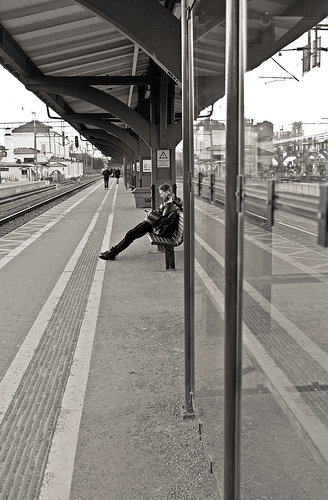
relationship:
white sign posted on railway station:
[142, 158, 151, 173] [0, 0, 326, 500]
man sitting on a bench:
[99, 183, 175, 260] [152, 220, 182, 269]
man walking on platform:
[102, 166, 111, 187] [70, 184, 129, 217]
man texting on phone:
[99, 183, 178, 260] [145, 209, 150, 215]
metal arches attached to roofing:
[27, 77, 157, 159] [1, 0, 171, 112]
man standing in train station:
[99, 166, 108, 186] [2, 0, 326, 281]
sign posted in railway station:
[151, 143, 201, 172] [0, 0, 326, 500]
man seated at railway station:
[99, 183, 175, 260] [0, 0, 327, 498]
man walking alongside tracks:
[102, 166, 111, 187] [0, 169, 104, 243]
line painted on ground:
[39, 179, 120, 497] [3, 171, 325, 494]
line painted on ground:
[0, 178, 119, 500] [3, 171, 325, 494]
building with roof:
[12, 120, 83, 179] [11, 120, 48, 132]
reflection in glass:
[188, 112, 272, 182] [190, 28, 315, 493]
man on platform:
[99, 183, 175, 260] [0, 162, 326, 497]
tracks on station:
[0, 172, 105, 226] [4, 1, 327, 490]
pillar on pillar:
[182, 0, 195, 412] [151, 148, 177, 207]